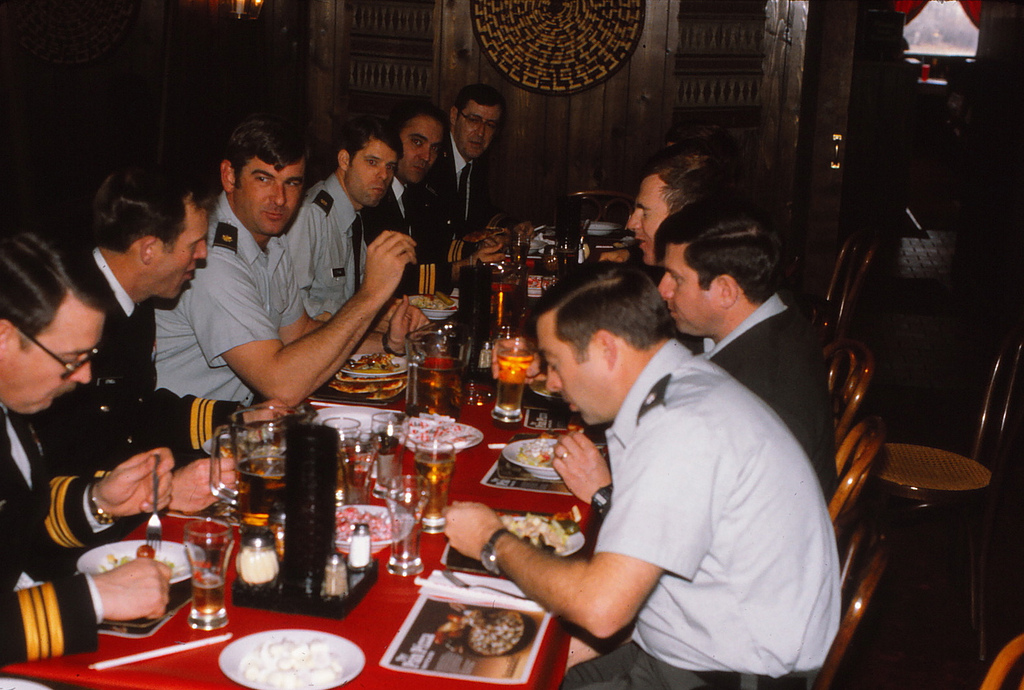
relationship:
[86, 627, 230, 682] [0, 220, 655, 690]
straw in plate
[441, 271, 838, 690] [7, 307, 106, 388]
eating in glasses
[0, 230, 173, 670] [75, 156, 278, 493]
man wearing blue uniform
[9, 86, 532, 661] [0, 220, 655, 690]
military men sitting at plate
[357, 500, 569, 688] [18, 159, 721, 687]
placemat on table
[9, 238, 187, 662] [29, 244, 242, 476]
man wearing a blue uniform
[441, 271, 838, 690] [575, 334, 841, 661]
eating wearing a shirt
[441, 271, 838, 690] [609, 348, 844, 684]
eating with a rounded back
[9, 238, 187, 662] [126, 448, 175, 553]
man holding fork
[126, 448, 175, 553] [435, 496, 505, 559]
fork in left hand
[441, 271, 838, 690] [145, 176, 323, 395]
eating wearing a white uniform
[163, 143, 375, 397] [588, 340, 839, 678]
man wearing a shirt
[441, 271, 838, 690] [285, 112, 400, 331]
eating wearing a white uniform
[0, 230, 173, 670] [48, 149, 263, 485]
man wearing a blue uniform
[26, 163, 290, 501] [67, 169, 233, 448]
man wearing blue uniform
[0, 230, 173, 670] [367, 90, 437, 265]
man wearing blue uniform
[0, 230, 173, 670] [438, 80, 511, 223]
man wearing blue uniform